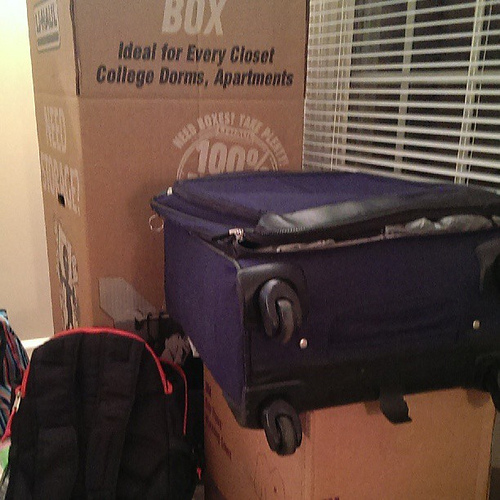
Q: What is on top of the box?
A: A suitcase.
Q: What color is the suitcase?
A: Blue.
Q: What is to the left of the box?
A: A backpack.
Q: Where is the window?
A: Next to the suitcase.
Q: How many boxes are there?
A: Two.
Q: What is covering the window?
A: Blinds.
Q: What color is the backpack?
A: Black.